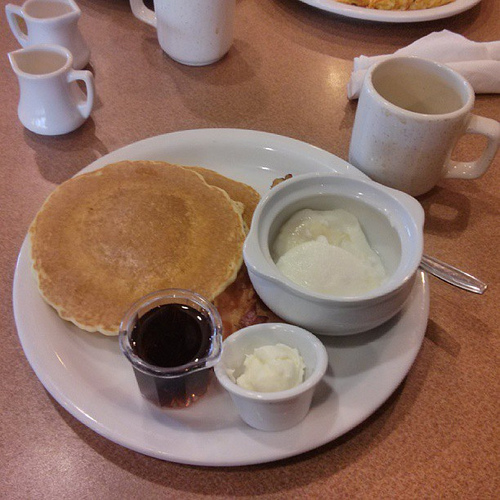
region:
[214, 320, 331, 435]
butter in a small white bowl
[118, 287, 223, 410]
maple syrup in a small white bowl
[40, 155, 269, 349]
stack of pancakes on a plate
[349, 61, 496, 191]
an empty white coffee mug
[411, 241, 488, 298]
silver handle to a utensil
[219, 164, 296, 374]
strip of bacon next to pancakes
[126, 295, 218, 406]
maple syrup is sticky and brown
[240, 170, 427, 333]
a large white bowl with butter inside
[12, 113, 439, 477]
plate with a pancake breakfast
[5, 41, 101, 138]
a small white pitcher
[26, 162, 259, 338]
a stack of pancakes on a plate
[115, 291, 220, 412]
maple syrup in a container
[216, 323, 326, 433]
butter in a container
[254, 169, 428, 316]
grits in a bowl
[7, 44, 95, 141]
a white cream pitcher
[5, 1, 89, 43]
a white cream pitcher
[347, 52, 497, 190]
a white coffee cup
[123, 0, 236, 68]
a white coffee cup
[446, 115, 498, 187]
the handle of a coffee cup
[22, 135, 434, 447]
breakfast on a white plate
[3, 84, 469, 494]
a breakfast plate on a table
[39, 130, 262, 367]
these are pancakes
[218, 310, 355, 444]
this is a small cup of butter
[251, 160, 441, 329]
this bowl has egg whites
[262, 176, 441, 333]
there are poached eggs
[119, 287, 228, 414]
a cup of syrup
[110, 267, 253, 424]
maple syrup in a cup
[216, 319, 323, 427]
a dollop of butter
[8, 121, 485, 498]
the plate is round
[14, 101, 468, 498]
the plate is white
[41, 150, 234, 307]
food on the plate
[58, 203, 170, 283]
brown food on plate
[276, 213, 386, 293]
food in a bowl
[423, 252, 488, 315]
handle of the spoon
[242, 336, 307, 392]
white stuff in the cup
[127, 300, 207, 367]
syrup in the glass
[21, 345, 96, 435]
white plate under food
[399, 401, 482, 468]
table under the plate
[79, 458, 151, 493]
shadow of the plate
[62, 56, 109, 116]
handle of the cup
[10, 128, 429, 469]
a large white plate on the table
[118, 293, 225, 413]
a plastic cup with syrup in it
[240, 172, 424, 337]
a round white bowl on a white plate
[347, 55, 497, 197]
a white coffee cup on the table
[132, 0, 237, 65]
a white coffee cup on the table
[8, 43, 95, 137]
a small white cream pitcher on table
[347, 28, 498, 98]
a white napkin on the table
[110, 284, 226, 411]
container of syrup on plate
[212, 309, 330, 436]
container of butter on plate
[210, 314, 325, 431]
container with butter is white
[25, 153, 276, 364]
stack of pancakes on plate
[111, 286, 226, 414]
container for syrup is clear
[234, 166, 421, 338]
bowl on top of plate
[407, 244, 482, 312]
silverware on top of plate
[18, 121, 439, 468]
white plate on table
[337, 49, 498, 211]
coffee mug next to plate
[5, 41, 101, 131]
creamer pitcher on table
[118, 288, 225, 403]
small clear container of syrup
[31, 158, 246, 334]
round pancake on a plate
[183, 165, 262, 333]
round pancake on a plate